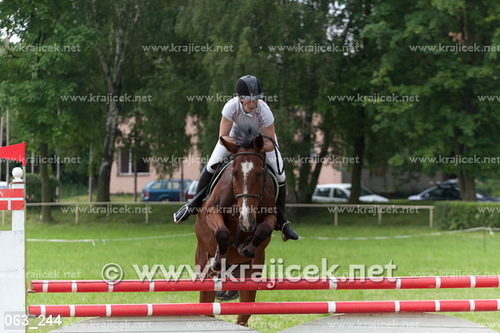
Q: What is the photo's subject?
A: Horse jumping.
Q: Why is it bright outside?
A: It's daytime.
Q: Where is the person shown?
A: On the horse.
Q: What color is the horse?
A: Brown.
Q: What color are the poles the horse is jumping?
A: Red.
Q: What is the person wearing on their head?
A: Helmet.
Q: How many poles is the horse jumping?
A: Two.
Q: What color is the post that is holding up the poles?
A: White.